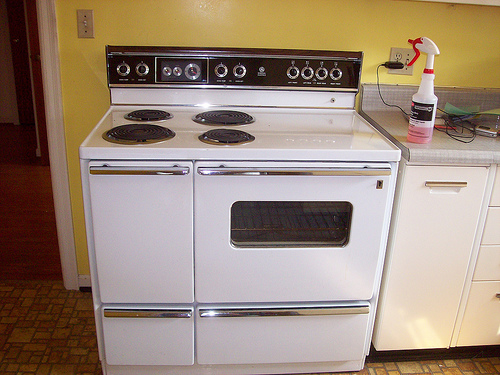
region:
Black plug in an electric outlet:
[372, 41, 420, 79]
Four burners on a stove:
[95, 95, 267, 155]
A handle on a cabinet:
[416, 165, 471, 197]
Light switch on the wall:
[67, 1, 97, 43]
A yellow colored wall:
[47, 0, 494, 276]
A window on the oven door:
[220, 190, 360, 255]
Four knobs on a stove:
[277, 55, 347, 86]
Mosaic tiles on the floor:
[1, 274, 498, 371]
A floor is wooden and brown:
[0, 156, 70, 277]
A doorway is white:
[30, 0, 82, 298]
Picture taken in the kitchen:
[7, 5, 492, 368]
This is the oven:
[196, 163, 384, 316]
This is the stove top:
[98, 85, 258, 167]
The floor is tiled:
[3, 280, 93, 374]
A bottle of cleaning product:
[407, 36, 441, 143]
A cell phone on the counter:
[465, 105, 498, 150]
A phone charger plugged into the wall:
[379, 50, 476, 155]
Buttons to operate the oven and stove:
[109, 54, 351, 85]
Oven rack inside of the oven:
[233, 205, 343, 239]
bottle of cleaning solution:
[405, 34, 439, 146]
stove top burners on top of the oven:
[101, 99, 258, 148]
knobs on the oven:
[107, 46, 357, 94]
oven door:
[197, 158, 387, 311]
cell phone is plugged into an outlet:
[373, 60, 495, 139]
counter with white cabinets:
[353, 82, 498, 351]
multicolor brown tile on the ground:
[0, 276, 495, 373]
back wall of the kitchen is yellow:
[52, 5, 497, 280]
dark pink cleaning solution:
[403, 120, 433, 142]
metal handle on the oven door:
[193, 164, 386, 177]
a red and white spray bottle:
[405, 31, 446, 142]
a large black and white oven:
[82, 43, 389, 373]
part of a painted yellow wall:
[122, 0, 338, 40]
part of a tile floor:
[0, 278, 97, 373]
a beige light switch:
[72, 8, 99, 41]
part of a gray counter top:
[357, 85, 499, 158]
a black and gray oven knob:
[233, 63, 248, 76]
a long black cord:
[375, 56, 477, 148]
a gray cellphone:
[464, 123, 497, 138]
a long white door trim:
[36, 4, 86, 292]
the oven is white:
[82, 49, 390, 370]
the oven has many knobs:
[109, 53, 361, 85]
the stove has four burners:
[105, 110, 250, 145]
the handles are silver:
[87, 163, 388, 320]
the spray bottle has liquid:
[404, 38, 442, 147]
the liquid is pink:
[403, 125, 428, 143]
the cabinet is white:
[373, 165, 499, 352]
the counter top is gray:
[358, 87, 499, 164]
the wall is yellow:
[56, 0, 497, 278]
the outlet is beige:
[386, 48, 414, 72]